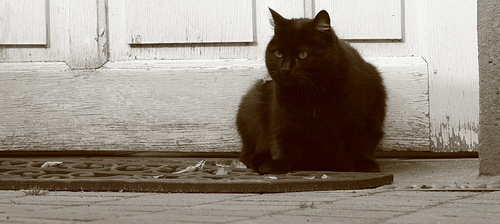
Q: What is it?
A: Cat.